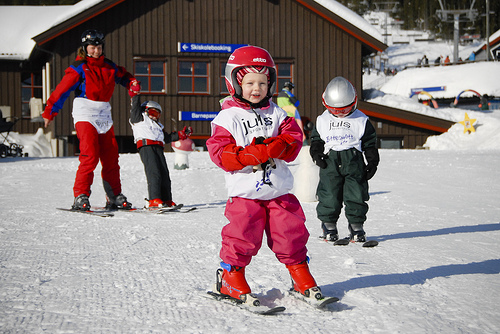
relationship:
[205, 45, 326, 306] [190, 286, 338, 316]
child on skis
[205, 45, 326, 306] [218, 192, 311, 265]
child wearing snow pants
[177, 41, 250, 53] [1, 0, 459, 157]
sign on building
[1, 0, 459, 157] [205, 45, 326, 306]
building behind child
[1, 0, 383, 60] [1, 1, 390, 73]
snow on roof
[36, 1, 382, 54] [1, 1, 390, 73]
stripe on roof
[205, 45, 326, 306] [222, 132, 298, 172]
child wearing mittens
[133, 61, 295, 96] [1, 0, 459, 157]
windows on building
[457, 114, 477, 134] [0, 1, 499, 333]
star in snow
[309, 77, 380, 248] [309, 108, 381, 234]
skier in suit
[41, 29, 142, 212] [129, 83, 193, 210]
mother with child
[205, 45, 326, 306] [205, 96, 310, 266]
child in suit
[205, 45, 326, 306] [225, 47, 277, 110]
child has helmet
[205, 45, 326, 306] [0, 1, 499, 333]
child on snow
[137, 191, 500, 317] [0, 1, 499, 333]
shadows on snow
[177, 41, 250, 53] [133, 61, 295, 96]
sign above windows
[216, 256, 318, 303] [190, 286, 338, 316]
ski boots on skis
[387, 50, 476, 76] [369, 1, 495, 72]
people by ski lift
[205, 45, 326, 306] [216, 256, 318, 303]
child wearing ski boots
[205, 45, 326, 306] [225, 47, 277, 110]
child wearing helmet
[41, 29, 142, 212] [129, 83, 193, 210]
mother helping child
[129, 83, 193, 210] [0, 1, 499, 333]
child falling on snow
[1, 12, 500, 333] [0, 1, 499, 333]
ground covered in snow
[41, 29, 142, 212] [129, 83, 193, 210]
mother holding up child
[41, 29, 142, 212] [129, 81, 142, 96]
mother holding hand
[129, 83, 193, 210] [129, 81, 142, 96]
child has hand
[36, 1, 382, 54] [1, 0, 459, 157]
stripe on building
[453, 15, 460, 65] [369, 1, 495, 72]
pole for ski lift